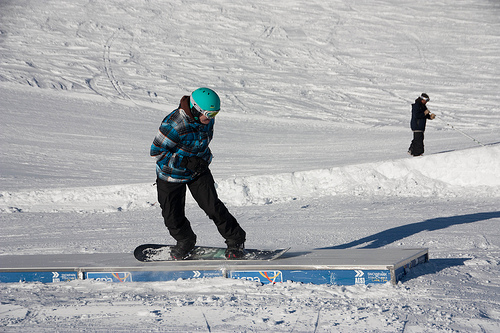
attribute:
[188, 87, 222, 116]
helmet — green, blue-green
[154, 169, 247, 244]
pants — black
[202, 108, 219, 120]
goggles — white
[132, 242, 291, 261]
snowboard — black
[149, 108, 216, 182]
jacket — blue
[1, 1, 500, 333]
snow — powdery, sloped, untouched, white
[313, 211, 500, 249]
shadow — dark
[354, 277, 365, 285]
letters — white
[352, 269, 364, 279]
arrows — white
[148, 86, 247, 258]
person — snowboarding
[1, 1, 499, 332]
ground — snow-covered